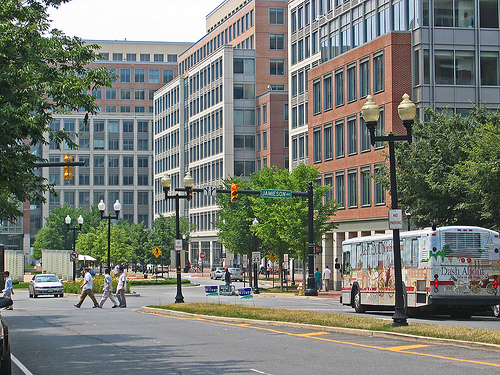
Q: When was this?
A: Daytime.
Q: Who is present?
A: Pedestrians.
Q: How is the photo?
A: Clear.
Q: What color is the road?
A: Grey.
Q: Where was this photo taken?
A: In the city.